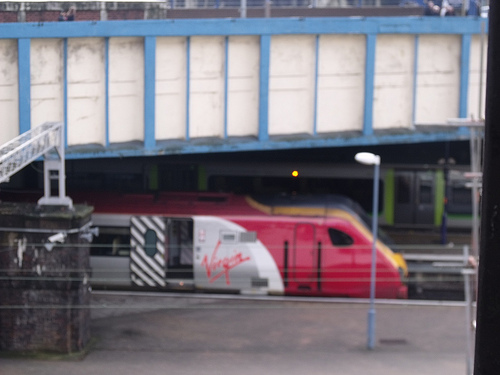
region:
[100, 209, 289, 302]
Train is white and tan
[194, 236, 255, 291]
Letters on side of train says "Virgin"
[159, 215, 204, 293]
Door of train is open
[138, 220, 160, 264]
Window of door of train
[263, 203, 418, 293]
Train is red and yellow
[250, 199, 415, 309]
Train has a yellow stripe on the center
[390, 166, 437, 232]
Door of train is grey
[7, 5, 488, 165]
Bridge of train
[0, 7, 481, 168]
Bridge has blue structure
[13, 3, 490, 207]
Bridge is over train station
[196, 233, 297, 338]
train says virgin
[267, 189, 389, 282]
red orange and blue train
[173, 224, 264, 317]
grey train with red lettering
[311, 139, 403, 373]
a light post at station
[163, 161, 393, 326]
two trains on the track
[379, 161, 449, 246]
green and grey train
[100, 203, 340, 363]
door open on train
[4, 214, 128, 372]
big column on train station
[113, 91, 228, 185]
this is blue and white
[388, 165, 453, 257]
the doors are closed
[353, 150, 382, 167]
a white street light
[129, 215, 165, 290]
the black and white train door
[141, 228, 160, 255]
a window on the train door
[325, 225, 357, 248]
a window on the train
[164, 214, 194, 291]
the open doorway to the train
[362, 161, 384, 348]
a gray street light pole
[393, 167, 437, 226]
the gray doors on a train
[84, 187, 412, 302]
a red and gray train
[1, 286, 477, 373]
a gray sidewalk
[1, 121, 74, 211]
a white metal beam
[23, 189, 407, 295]
Red train moving on railroad tracks.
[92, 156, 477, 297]
Two trains underneath a bridge.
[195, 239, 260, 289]
Virgin commercial logo on side of red train.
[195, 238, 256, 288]
Virgin logo on the gray side of red train.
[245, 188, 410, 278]
Black and yellow on top of red train.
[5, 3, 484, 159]
White and blue train above trains on tracks.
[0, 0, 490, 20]
People standing on the bridge.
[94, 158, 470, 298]
Two moving trains underneath blue and white bridge.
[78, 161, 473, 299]
Trains moving on railroad tracks.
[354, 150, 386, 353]
Lamp on a gray pole.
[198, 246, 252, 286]
an adverstisment on the side of the train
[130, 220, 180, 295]
a black and white striped door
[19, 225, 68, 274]
torn paper stuck to the wall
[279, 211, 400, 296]
a red super train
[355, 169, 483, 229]
a silver subway train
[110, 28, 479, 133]
blue supports on the bridge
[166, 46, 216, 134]
white panels on the bridge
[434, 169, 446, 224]
a yellow vertical line on the train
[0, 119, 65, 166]
a metal bridge over the depot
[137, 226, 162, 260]
an oval window on the train